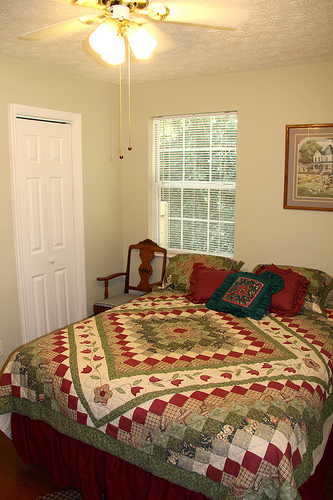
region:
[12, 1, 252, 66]
A fan on the ceiling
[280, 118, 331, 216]
A framed painting on the wall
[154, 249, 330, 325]
Pillows are on the bed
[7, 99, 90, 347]
A white wooden door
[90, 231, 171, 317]
A chair against the wall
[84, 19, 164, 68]
Lights are turned on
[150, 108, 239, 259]
Blinds over a window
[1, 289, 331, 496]
A bedspread over the bed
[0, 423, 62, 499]
A brown wooden floor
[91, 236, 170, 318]
The chair is brown and wooden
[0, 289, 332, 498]
A double bed with decorative bedspread.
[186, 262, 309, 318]
Two red pillows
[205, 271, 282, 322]
A cushion with decorative green cover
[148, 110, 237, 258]
A window letting in sunlight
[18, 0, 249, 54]
A white ceiling fan with lights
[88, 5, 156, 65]
Lights under the ceiling fan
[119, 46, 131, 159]
Chords to pull to switch lights on and off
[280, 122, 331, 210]
A picture frame on the wall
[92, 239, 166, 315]
A wooden chair in the corner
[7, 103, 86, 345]
A white door with two shutters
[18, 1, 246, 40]
white ceiling fan with lights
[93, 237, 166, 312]
wooden chair with checkered seat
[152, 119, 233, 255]
window with white mini blinds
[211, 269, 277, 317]
green pillow on the bed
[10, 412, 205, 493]
red bedskirt at foot of bed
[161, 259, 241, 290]
green pillow at head of bed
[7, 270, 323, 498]
patchwork quilt covering bed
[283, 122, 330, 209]
wooden frame around picture on wall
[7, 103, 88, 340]
white door with white door frame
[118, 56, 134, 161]
chains with round knobs on ends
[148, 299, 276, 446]
Blanket on the bed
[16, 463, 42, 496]
Floor is made of wood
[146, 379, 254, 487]
Design on the bed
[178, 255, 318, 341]
Pillows on the bed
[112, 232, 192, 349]
Chair sitting beside the bed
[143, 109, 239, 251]
Blind on the window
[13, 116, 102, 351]
Door on the wall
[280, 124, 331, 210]
Picture on the wall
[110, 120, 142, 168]
Pulls on the fan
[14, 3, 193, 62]
Ceiling fan to light and cool the room.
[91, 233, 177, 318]
Chair next to the bed.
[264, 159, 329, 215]
Picture on the wall.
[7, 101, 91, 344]
Closet door in the bedroom.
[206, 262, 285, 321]
A green pillow on the bed.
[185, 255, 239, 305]
A burgandy pillow on the bed.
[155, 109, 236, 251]
Mini blinds hung on the window.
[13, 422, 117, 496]
Burgandy dust ruffle on the bed.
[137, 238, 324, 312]
A total of five pillows on the bed.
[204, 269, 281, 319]
a green throw pillow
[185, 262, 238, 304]
a red throw pillow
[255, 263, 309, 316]
a red throw pillow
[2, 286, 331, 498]
a green red and white quilt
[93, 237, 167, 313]
a wooden arm chair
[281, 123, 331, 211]
a framed art print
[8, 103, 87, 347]
a closed white door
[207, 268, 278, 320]
a blue throw pillow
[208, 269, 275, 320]
a blue pillow on the bed center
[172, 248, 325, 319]
pillow on the back of a bed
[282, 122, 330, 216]
a picture hanging on a wall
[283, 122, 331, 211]
a picture in a frame